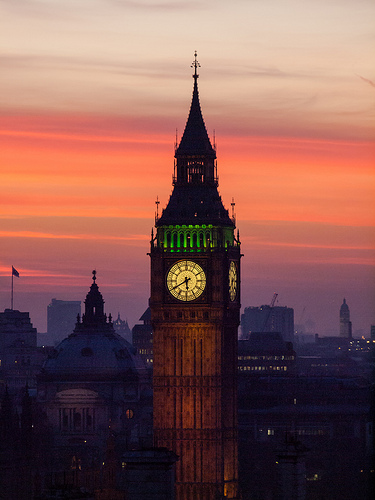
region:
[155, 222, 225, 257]
green light on side of tower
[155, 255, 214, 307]
large clock on side of tower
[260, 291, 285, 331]
large metal construction crane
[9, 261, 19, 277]
flag flying on pole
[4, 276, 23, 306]
flag pole on roof of building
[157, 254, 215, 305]
yellow tower with black hands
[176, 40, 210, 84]
design on top of clock tower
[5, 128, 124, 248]
sky with setting evening sun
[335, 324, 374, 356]
city lights in distance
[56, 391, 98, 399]
writing on front of building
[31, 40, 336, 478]
This is not America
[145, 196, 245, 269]
Green light on the tower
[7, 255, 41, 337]
A flag on top of this building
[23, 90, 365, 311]
The time is sunset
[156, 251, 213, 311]
6:40 is on the clock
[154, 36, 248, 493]
This is the tallest building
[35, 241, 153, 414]
This is the second tallest building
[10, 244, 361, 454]
There are many buildings pictured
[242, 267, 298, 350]
Construction is happening in the background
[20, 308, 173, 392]
A circular dome window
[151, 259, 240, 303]
two clocks on sides of tower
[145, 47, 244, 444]
clock tower on top of a building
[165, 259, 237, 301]
clocks on the tower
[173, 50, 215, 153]
steeple on top of clock tower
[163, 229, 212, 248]
green columns above the clock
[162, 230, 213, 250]
eight green columns on the clock tower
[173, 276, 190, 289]
black minute and hour hands on face of clock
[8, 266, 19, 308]
flag on top of building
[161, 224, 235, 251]
green lights on the columns above the clock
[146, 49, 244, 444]
historical clock tower building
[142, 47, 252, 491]
Big Ben clock tower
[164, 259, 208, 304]
a large lighted clockface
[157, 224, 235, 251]
green lights illuminate part of the tower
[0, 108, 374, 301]
an orange sunset sky in the background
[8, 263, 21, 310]
a flag and pole in the distance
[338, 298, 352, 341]
a skyscraper in the background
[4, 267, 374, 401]
tall city buildings in the background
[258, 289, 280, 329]
a construction crane in the background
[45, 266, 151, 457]
a building with a dome next to Big Ben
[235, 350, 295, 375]
the lights inside the building are on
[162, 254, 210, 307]
glowing clock on tower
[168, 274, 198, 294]
two hands on clock face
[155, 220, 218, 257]
green lights on tower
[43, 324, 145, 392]
dome on old building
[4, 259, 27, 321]
flag and pole on building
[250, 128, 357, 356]
multi colored sky above city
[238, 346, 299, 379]
lights on city building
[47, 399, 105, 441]
double columns on building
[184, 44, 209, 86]
rod on top of tower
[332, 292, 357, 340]
skyscraper on city horizon